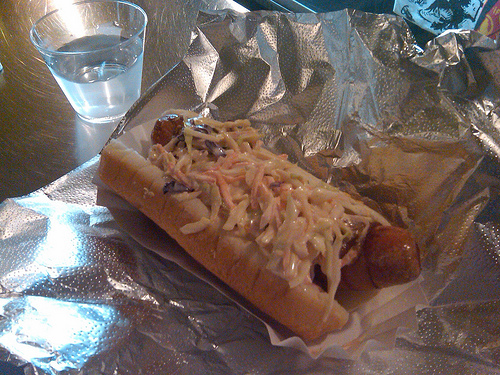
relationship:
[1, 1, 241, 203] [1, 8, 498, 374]
table under foil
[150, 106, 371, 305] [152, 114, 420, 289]
cabbage on top of hot dog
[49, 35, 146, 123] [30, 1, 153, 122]
water inside cup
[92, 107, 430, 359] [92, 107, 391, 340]
paper holder under bun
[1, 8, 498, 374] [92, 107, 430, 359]
foil under paper holder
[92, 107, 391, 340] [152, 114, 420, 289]
bun holding hot dog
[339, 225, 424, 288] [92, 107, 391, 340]
hot dog end sticking out of bun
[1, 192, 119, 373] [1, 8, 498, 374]
reflection on top of foil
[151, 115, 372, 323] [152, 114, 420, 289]
cole slaw on top of hot dog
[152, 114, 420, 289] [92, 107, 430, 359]
hot dog on top of paper holder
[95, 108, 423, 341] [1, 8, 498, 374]
food on top of foil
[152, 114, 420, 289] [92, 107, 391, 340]
hot dog inside bun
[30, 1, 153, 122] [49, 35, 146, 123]
cup full of water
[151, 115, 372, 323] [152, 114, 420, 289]
cole slaw topping hot dog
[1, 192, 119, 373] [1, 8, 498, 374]
reflection on surface of foil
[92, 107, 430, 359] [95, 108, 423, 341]
paper holder under food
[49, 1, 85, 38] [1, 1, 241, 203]
light reflected on table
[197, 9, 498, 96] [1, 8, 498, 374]
edge of foil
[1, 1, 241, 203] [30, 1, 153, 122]
table under cup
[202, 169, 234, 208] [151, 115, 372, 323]
carrot mixed into cole slaw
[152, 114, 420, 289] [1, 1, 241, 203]
hot dog on top of table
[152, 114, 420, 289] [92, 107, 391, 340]
hot dog on top of bun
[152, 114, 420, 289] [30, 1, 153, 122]
hot dog near cup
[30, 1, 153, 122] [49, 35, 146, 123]
cup filled with water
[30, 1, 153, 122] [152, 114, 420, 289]
cup near hot dog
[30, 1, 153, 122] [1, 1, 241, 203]
cup on top of table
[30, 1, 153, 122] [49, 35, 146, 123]
cup holding water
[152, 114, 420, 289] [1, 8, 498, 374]
hot dog sitting on foil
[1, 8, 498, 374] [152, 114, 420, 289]
foil wrapper for hot dog